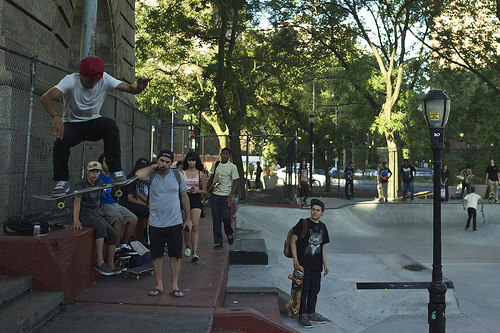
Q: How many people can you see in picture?
A: 18.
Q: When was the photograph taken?
A: Mid afternoon.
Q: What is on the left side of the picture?
A: A building.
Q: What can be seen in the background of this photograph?
A: Trees.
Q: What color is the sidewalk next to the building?
A: Red.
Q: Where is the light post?
A: Front right side of photograph.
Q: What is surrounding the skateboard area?
A: A chain link fence.